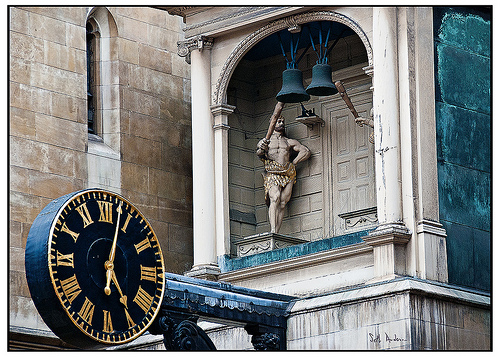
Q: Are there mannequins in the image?
A: No, there are no mannequins.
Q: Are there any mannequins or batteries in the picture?
A: No, there are no mannequins or batteries.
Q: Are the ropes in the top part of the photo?
A: Yes, the ropes are in the top of the image.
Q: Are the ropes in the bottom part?
A: No, the ropes are in the top of the image.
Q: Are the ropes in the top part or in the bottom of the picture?
A: The ropes are in the top of the image.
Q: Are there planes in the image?
A: No, there are no planes.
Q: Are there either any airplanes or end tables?
A: No, there are no airplanes or end tables.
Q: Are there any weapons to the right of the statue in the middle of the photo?
A: Yes, there is a weapon to the right of the statue.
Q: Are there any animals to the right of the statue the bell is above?
A: No, there is a weapon to the right of the statue.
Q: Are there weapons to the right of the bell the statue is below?
A: Yes, there is a weapon to the right of the bell.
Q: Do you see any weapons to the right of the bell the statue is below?
A: Yes, there is a weapon to the right of the bell.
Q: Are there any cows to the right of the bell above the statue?
A: No, there is a weapon to the right of the bell.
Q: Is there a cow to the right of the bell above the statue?
A: No, there is a weapon to the right of the bell.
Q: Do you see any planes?
A: No, there are no planes.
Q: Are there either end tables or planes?
A: No, there are no planes or end tables.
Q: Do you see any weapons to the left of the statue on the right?
A: Yes, there is a weapon to the left of the statue.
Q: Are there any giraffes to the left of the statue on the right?
A: No, there is a weapon to the left of the statue.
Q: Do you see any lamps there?
A: No, there are no lamps.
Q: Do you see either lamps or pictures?
A: No, there are no lamps or pictures.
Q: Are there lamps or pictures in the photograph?
A: No, there are no lamps or pictures.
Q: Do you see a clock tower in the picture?
A: No, there are no clock towers.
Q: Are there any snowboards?
A: No, there are no snowboards.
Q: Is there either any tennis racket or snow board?
A: No, there are no snowboards or rackets.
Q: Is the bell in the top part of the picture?
A: Yes, the bell is in the top of the image.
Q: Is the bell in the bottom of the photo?
A: No, the bell is in the top of the image.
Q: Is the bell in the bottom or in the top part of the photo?
A: The bell is in the top of the image.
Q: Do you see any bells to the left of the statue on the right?
A: Yes, there is a bell to the left of the statue.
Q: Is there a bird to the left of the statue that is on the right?
A: No, there is a bell to the left of the statue.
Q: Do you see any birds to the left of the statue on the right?
A: No, there is a bell to the left of the statue.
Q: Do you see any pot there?
A: No, there are no pots.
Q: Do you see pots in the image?
A: No, there are no pots.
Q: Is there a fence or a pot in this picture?
A: No, there are no pots or fences.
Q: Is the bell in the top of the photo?
A: Yes, the bell is in the top of the image.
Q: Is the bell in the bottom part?
A: No, the bell is in the top of the image.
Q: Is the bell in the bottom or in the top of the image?
A: The bell is in the top of the image.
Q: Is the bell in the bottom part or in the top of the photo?
A: The bell is in the top of the image.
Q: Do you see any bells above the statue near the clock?
A: Yes, there is a bell above the statue.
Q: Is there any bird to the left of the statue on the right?
A: No, there is a bell to the left of the statue.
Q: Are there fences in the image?
A: No, there are no fences.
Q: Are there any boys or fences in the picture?
A: No, there are no fences or boys.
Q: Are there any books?
A: No, there are no books.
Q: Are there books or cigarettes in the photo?
A: No, there are no books or cigarettes.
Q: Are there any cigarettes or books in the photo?
A: No, there are no books or cigarettes.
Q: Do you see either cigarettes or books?
A: No, there are no books or cigarettes.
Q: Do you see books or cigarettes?
A: No, there are no books or cigarettes.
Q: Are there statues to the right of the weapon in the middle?
A: Yes, there is a statue to the right of the weapon.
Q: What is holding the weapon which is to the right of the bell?
A: The statue is holding the weapon.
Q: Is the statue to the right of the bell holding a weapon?
A: Yes, the statue is holding a weapon.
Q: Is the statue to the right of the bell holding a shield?
A: No, the statue is holding a weapon.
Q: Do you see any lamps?
A: No, there are no lamps.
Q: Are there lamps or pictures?
A: No, there are no lamps or pictures.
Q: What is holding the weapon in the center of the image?
A: The statue is holding the weapon.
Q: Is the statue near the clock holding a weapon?
A: Yes, the statue is holding a weapon.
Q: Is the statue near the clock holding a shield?
A: No, the statue is holding a weapon.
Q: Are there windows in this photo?
A: Yes, there is a window.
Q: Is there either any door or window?
A: Yes, there is a window.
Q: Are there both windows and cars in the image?
A: No, there is a window but no cars.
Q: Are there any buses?
A: No, there are no buses.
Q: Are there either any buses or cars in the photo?
A: No, there are no buses or cars.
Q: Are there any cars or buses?
A: No, there are no buses or cars.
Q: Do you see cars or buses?
A: No, there are no buses or cars.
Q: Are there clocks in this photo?
A: Yes, there is a clock.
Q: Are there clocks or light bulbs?
A: Yes, there is a clock.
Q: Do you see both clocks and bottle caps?
A: No, there is a clock but no bottle caps.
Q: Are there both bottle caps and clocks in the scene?
A: No, there is a clock but no bottle caps.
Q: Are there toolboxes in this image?
A: No, there are no toolboxes.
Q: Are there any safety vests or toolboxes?
A: No, there are no toolboxes or safety vests.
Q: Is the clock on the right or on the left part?
A: The clock is on the left of the image.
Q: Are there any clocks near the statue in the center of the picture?
A: Yes, there is a clock near the statue.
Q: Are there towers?
A: No, there are no towers.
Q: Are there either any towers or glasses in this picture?
A: No, there are no towers or glasses.